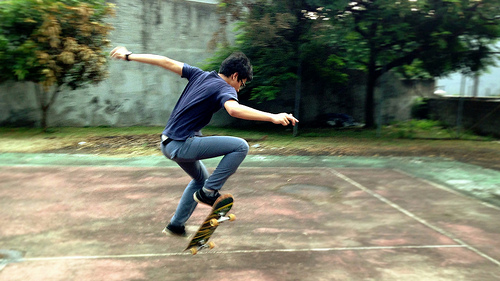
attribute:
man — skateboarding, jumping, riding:
[110, 46, 300, 238]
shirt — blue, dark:
[163, 65, 239, 139]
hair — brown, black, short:
[218, 50, 253, 81]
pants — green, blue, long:
[162, 136, 249, 222]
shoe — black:
[162, 220, 193, 239]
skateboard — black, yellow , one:
[184, 194, 235, 256]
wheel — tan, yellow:
[210, 217, 219, 227]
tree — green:
[2, 3, 117, 132]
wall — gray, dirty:
[2, 1, 433, 128]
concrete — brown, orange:
[3, 161, 499, 279]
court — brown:
[2, 169, 492, 274]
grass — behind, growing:
[3, 122, 499, 153]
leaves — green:
[3, 4, 113, 83]